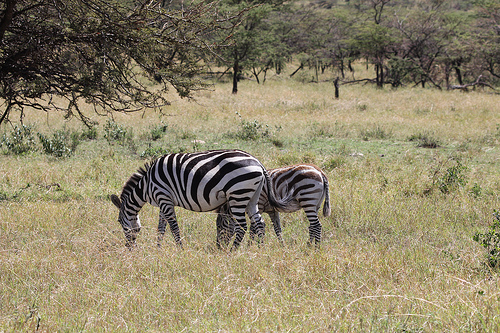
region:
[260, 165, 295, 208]
zebra tail touching zebra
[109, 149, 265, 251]
black and white zebra is grazing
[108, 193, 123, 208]
black ear on zebra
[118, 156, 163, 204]
mane on zebra neck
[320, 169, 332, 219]
zebra tail is hanging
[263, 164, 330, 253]
zebra standing behind another zebra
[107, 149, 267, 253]
zebra standing in front of another zebra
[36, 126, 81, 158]
tall green plants behind zebras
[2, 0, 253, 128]
tree above zebra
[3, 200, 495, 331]
grass is brown and dry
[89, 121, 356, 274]
two zebras grazing in grass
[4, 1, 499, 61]
trees behind the zebras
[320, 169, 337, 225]
tail of a zebra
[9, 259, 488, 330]
brownish green grass on a field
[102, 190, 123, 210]
left ear of a zebra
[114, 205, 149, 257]
side view face of a zebra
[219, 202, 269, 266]
back legs of a zebra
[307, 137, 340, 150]
patch of green grass in field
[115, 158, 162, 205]
mane of a zebra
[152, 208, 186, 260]
front legs of a zebra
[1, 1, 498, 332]
two zebras grazing in the African Plains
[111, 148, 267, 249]
a black and white zebra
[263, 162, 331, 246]
a brown and white zebra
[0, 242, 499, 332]
tall grazing grass of the plains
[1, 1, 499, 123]
tall trees near the gassy fields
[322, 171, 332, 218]
the tail of a young zebra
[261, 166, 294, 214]
the black tail of an adult zebra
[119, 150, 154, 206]
long hair on the neck of the zebra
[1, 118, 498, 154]
low shrubs growing in the grass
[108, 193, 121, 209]
the ear of a zebra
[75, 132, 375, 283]
Two zebras are eating.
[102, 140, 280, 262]
The larger zebra is in the foreground.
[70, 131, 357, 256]
The zebras have stripes.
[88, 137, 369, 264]
The zebras are black and white.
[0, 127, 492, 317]
The zebras stand in grass.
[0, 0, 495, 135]
Trees are in the background.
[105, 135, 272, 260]
The zebras' heads are bent.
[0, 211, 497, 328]
The grass is tall.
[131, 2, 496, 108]
The trees are green.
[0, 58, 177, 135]
The tree's branches are bare.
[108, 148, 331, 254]
The zebra are grazing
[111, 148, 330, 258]
Zebra are black and white striped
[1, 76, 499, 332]
Grass is tall and yellow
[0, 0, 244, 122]
Tree is covered in leafless branches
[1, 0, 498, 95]
Trees line the background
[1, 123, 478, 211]
Small bushes grow up through the grass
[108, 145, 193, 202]
Zebra mane is black and white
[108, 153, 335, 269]
The closer zebra is larger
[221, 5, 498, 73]
Trees in distance have many more leaves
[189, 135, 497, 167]
Small patch of green grass